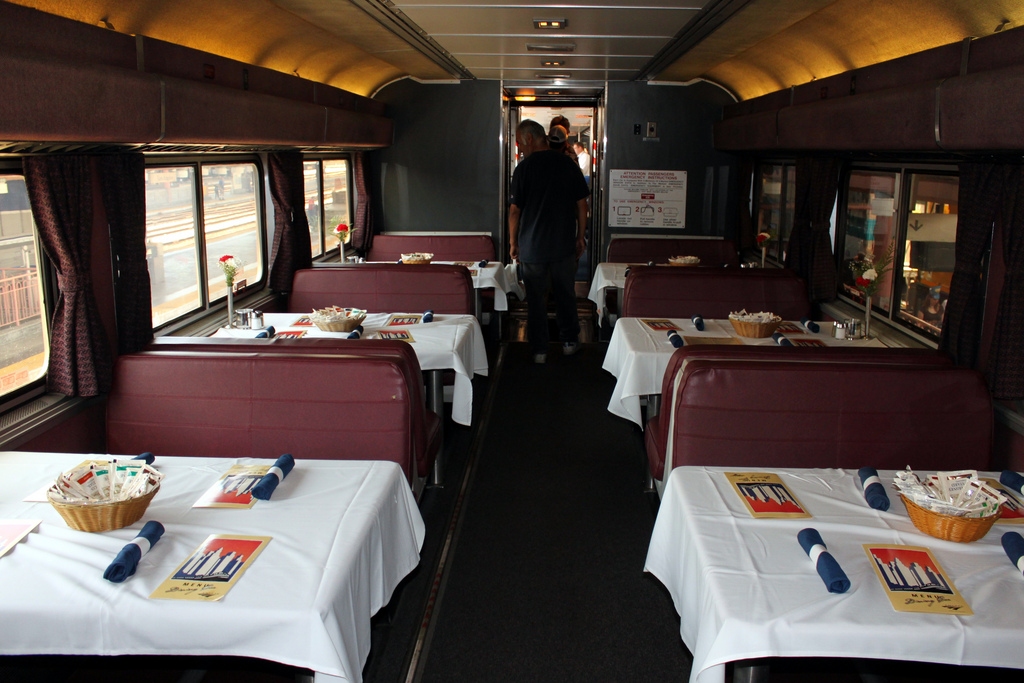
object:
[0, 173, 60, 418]
window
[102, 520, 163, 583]
blue cloth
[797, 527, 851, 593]
blue cloth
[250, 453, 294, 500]
blue cloth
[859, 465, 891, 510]
blue cloth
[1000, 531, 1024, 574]
blue cloth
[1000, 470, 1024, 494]
blue cloth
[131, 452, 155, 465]
blue cloth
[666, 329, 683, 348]
blue cloth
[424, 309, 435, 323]
blue cloth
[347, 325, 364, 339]
blue cloth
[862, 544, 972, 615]
menu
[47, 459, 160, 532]
basket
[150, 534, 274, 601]
menu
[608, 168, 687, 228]
white sign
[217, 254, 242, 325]
flower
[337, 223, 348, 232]
flower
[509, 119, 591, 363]
man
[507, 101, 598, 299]
doorway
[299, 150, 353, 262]
window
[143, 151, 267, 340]
window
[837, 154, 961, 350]
window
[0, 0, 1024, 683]
train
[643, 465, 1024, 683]
table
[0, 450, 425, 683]
table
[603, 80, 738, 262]
wall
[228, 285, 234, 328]
vase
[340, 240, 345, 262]
vase